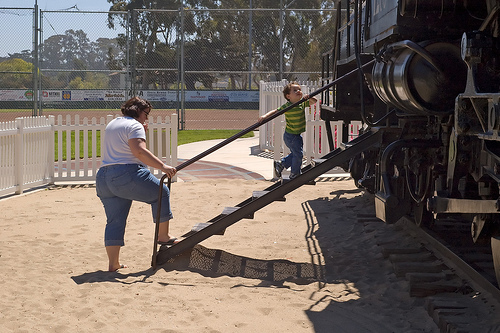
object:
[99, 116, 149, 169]
white shirt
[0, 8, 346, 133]
wall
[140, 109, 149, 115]
eyeglasses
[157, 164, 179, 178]
hand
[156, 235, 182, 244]
foot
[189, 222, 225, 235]
step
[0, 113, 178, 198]
fence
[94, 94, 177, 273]
lady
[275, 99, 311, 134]
shirt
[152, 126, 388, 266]
stairs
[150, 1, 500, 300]
train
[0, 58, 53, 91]
trees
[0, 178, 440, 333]
sand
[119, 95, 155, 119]
hair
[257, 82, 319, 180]
boy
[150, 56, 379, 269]
rail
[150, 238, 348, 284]
shadow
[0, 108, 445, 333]
ground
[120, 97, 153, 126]
head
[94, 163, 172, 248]
pants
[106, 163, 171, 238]
legs